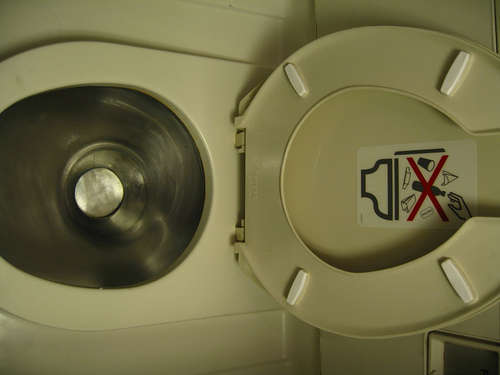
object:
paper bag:
[398, 192, 419, 212]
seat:
[4, 40, 233, 323]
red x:
[405, 152, 451, 225]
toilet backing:
[233, 19, 498, 337]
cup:
[416, 154, 440, 174]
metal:
[1, 126, 191, 250]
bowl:
[0, 70, 215, 293]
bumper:
[281, 60, 308, 100]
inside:
[3, 115, 174, 250]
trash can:
[423, 328, 498, 372]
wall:
[312, 2, 497, 373]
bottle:
[404, 178, 448, 198]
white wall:
[0, 308, 309, 373]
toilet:
[0, 26, 500, 350]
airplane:
[0, 0, 500, 375]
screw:
[232, 222, 252, 244]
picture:
[352, 138, 474, 231]